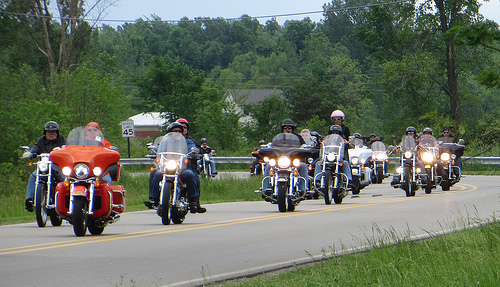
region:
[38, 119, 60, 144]
the head of a man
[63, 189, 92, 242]
the front wheel of a motorcycle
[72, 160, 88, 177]
the headlight of a motocycle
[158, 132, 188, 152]
the windshield of a motocycle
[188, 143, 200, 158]
the mirror of a motocycle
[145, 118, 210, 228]
two people on a motocycle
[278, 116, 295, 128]
a black motorcycle helmet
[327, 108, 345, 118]
a white motorcycle helmet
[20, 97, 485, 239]
several motorcycles riding down the road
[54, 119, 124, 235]
an orange motorcycle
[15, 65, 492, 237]
The people are all on motorcycles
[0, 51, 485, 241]
The people belong to a club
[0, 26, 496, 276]
The people are riding on the street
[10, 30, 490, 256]
The people are using the road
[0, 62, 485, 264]
The people are on big motorcycles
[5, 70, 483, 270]
The people are all driving safely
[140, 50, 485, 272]
The people are all wearing helmets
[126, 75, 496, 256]
The motorcycles have the headlights on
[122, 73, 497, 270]
The motorcycles are grouped close together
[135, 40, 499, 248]
The motorcyclists are enjoying the day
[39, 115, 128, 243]
the motorcycle is orange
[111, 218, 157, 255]
the lines are yellow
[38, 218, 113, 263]
the lines are yellow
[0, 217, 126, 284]
the lines are yellow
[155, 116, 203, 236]
This is a motorcyclist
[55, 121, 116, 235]
This is a motorcyclist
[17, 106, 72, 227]
This is a motorcyclist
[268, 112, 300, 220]
This is a motorcyclist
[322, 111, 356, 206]
This is a motorcyclist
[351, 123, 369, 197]
This is a motorcyclist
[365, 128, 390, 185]
This is a motorcyclist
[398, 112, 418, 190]
This is a motorcyclist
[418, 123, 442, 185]
This is a motorcyclist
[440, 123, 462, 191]
This is a motorcyclist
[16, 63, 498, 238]
group of motorcyles on the road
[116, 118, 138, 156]
45 mph speed limit sign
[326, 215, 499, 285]
tall weeds growing alongside the road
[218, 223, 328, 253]
Well maintained asphalt road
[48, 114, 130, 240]
red motorcycle driving down the road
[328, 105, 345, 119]
regulation sized white motorcycle helmet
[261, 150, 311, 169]
row of lit up motorcycle headlights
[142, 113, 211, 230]
motorcycle carrying two passengers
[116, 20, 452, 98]
tall, green, leafy trees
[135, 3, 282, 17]
perfect light blue sky